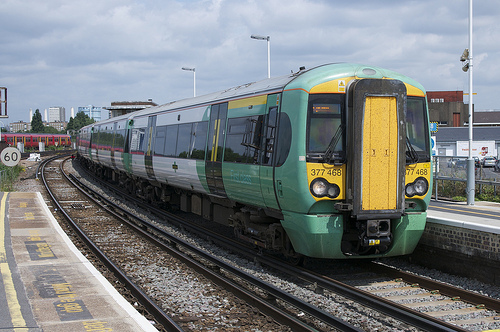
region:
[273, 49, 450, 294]
the train is yellow and green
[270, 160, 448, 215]
the headlights are off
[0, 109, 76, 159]
a red train in the background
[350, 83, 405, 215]
the door is yellow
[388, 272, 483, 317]
rocks on the tracks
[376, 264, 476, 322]
the rocks are grey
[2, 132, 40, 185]
the number 60 to the left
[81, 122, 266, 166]
the windows are dark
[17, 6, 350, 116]
the sky is overcast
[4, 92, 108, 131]
buildings in the distance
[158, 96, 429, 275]
green white and yellow train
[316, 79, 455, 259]
front of train is yellow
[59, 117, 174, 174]
white stripes on train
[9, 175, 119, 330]
white line on platform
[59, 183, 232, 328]
grey gravel between tracks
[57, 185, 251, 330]
brown railroad ties below train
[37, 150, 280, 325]
black rails below train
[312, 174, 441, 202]
train has white headlights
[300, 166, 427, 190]
black numbers on train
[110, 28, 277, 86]
white clouds in overcast sky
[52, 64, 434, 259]
a green and yellow train on the track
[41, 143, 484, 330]
the train tracks next to the platforms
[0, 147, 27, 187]
a sign next to the platform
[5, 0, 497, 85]
the white clouds in the sky on a sunny day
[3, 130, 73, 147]
a long red train on the track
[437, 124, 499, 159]
a building next to the parking lot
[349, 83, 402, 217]
a door in the front of the train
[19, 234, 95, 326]
writing on the platform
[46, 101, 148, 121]
buildings off in the distance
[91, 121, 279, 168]
windows along the side of the train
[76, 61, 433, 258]
A train driving down the tracks.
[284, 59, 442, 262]
A green and yellow train engine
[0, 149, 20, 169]
The number sixty on a sign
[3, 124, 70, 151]
A red train far away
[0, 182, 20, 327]
A yellow line painted on the sidewalk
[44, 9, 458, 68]
Lots of clouds in the sky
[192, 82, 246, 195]
Doors on the side of the train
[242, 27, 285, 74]
A very tall light pole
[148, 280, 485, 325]
two sets of tracks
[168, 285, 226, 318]
Gravel between the track are gray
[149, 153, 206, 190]
White on the side of the train